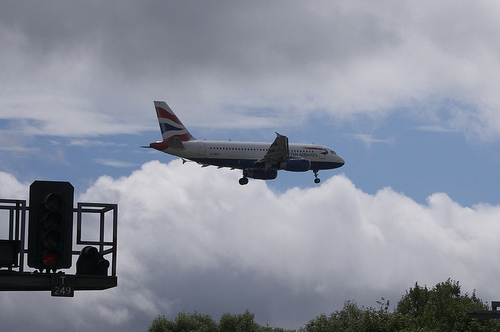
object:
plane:
[138, 100, 345, 186]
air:
[3, 4, 500, 309]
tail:
[153, 100, 197, 141]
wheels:
[313, 178, 320, 184]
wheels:
[239, 177, 249, 185]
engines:
[242, 156, 311, 180]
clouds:
[0, 0, 499, 332]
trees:
[144, 278, 499, 332]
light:
[27, 180, 75, 273]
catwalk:
[0, 199, 119, 291]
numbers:
[55, 287, 72, 296]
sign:
[51, 273, 75, 297]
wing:
[253, 131, 291, 170]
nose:
[337, 156, 345, 167]